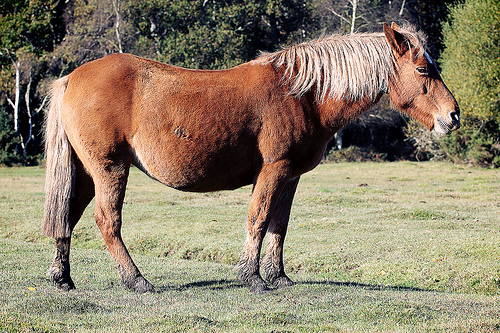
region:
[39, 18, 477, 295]
Big brown colored horse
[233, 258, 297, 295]
Black steady horse hooves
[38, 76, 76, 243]
Long wide beige tail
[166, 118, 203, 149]
Small scar on horse body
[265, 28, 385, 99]
Wide feathery horse mane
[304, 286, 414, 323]
Dried up grass patch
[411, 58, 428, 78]
A black opened eye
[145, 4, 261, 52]
Thick green bushy shrub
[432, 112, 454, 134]
Set of sharp teeth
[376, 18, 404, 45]
Two ears on alert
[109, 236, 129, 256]
edge of a tail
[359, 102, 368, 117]
part of a grass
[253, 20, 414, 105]
gray mane of an old horse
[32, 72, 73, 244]
long tail of a horse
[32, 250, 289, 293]
brown and black hooves of a horse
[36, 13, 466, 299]
an old brown and gray horse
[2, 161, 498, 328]
field of dying grass outside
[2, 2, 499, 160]
trees next to the field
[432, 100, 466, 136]
snout of the horse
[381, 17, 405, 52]
two ears on the horse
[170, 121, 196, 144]
spot on the horses coat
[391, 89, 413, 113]
jaw muscle of the horse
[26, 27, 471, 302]
Horse standing in a grassy field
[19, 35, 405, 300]
Horse standing in a grassy field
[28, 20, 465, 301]
Horse standing in a grassy field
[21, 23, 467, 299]
Horse standing in a grassy field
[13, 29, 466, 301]
Horse standing in a grassy field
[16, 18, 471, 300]
Horse standing in a grassy field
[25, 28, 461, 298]
Horse standing in a grassy field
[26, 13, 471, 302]
Horse standing in a grassy field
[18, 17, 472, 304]
Horse standing in a grassy field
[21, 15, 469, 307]
horse in field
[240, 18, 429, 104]
blonde horse mane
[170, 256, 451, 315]
horse shadow on ground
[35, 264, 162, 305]
bronw horse hoofs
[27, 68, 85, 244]
blonde horse tail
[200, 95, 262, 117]
brown horse fur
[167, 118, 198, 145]
brown mark on side of horse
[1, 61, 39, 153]
tree trunk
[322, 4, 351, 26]
branch on tree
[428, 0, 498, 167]
tall green bush